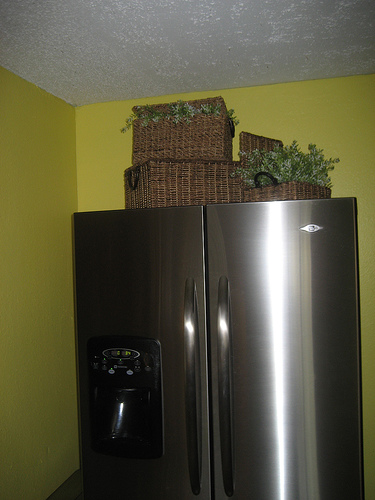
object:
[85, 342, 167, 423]
water filter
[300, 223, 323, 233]
logo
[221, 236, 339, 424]
stainless steel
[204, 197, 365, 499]
door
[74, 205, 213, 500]
door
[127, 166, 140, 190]
handle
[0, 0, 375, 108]
wall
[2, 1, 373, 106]
ceiling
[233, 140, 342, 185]
green plant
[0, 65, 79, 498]
wall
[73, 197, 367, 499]
fridge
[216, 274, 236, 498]
handle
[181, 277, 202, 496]
handle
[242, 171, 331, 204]
basket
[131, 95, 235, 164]
basket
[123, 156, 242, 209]
basket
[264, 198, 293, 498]
glare